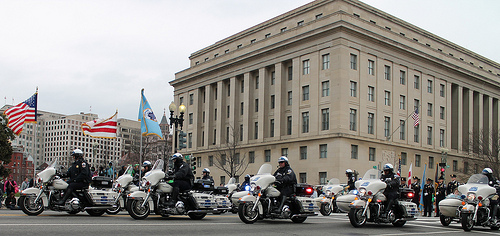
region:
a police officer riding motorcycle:
[237, 155, 319, 223]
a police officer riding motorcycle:
[127, 150, 217, 218]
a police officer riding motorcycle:
[19, 149, 114, 216]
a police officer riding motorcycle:
[106, 159, 158, 214]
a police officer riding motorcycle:
[436, 168, 499, 230]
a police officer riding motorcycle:
[330, 158, 417, 224]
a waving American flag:
[4, 92, 37, 137]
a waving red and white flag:
[80, 110, 116, 139]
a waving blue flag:
[136, 91, 164, 139]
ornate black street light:
[168, 99, 185, 153]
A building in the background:
[166, 0, 494, 195]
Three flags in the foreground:
[6, 75, 164, 199]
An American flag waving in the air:
[3, 82, 53, 202]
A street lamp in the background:
[162, 95, 189, 161]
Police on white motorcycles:
[13, 148, 496, 235]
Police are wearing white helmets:
[63, 135, 498, 196]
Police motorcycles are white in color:
[16, 138, 497, 231]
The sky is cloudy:
[6, 0, 498, 112]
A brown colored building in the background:
[2, 138, 40, 194]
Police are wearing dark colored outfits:
[56, 168, 417, 210]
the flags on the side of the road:
[3, 86, 165, 189]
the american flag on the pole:
[2, 86, 38, 133]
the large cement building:
[168, 0, 498, 192]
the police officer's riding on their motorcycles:
[20, 148, 499, 230]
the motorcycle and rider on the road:
[16, 147, 121, 212]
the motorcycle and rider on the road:
[126, 150, 212, 216]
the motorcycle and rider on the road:
[238, 156, 320, 223]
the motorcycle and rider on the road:
[349, 163, 408, 223]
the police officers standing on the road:
[399, 174, 460, 216]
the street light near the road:
[166, 100, 186, 155]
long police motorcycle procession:
[2, 143, 496, 229]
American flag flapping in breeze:
[6, 82, 41, 169]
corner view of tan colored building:
[172, 0, 494, 152]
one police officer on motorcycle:
[20, 145, 124, 217]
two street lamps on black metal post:
[166, 99, 186, 153]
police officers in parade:
[15, 141, 494, 231]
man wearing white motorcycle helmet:
[237, 153, 322, 223]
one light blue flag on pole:
[133, 85, 165, 162]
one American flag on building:
[379, 95, 426, 143]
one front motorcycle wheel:
[239, 197, 263, 224]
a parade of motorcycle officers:
[5, 4, 496, 229]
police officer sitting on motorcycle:
[233, 151, 323, 226]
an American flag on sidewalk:
[3, 83, 42, 188]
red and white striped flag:
[80, 107, 125, 171]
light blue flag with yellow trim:
[136, 85, 168, 164]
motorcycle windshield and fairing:
[245, 158, 277, 193]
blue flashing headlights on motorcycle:
[243, 181, 257, 194]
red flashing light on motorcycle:
[302, 182, 314, 195]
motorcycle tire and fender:
[237, 190, 265, 224]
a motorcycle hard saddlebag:
[294, 193, 324, 215]